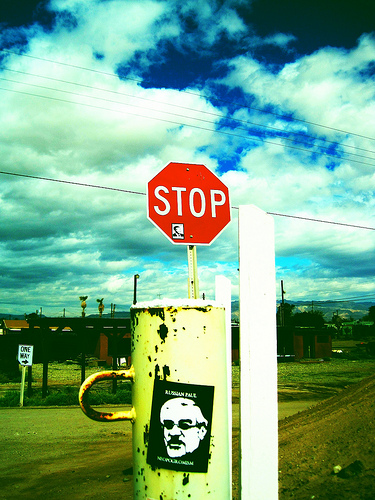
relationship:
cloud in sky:
[232, 44, 373, 171] [1, 3, 373, 303]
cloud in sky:
[36, 0, 258, 66] [1, 3, 373, 303]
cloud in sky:
[6, 46, 224, 173] [1, 3, 373, 303]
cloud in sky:
[211, 140, 374, 258] [1, 3, 373, 303]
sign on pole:
[149, 161, 231, 245] [186, 247, 198, 298]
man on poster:
[158, 397, 207, 457] [145, 379, 215, 474]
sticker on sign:
[170, 223, 184, 241] [149, 161, 231, 245]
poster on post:
[145, 379, 215, 474] [127, 302, 235, 497]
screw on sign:
[187, 164, 191, 172] [149, 161, 231, 245]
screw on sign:
[188, 235, 194, 240] [149, 161, 231, 245]